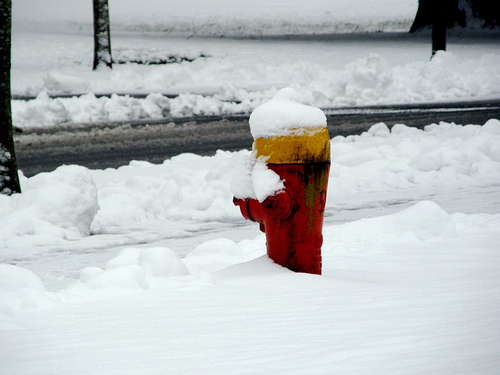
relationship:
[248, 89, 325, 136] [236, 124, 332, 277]
snow on top of fire hydrant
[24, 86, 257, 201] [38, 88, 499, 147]
snow on road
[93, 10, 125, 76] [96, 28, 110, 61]
trunk covered with snow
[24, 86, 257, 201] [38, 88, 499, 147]
snow next to road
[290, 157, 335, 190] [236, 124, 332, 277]
stains on fire hydrant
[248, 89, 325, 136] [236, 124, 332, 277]
snow on fire hydrant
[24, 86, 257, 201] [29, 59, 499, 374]
snow on ground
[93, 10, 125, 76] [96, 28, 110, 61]
trunk has snow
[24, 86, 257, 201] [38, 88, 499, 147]
snow on side of road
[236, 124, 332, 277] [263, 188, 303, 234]
fire hydrant has nozzle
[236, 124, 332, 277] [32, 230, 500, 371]
fire hydrant sitting in snow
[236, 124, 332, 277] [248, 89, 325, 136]
fire hydrant covered with snow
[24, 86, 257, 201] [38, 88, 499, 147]
snow on top of street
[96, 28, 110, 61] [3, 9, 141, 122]
snow on trees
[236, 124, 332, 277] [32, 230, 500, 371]
fire hydrant surrounded by snow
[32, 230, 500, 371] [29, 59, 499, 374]
snow on ground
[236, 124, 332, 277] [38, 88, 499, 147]
fire hydrant near road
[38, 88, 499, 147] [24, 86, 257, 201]
road covered with snow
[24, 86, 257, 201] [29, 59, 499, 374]
snow on top of ground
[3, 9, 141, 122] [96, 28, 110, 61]
trees has snow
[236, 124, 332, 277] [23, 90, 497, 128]
fire hydrant next to sidewalk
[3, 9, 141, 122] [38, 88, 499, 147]
trees by side of road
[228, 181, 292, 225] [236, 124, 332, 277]
hose attachment on fire hydrant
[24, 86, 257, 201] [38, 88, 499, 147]
snow side of road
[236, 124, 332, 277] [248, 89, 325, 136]
fire hydrant has snow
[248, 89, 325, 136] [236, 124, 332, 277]
snow atop fire hydrant